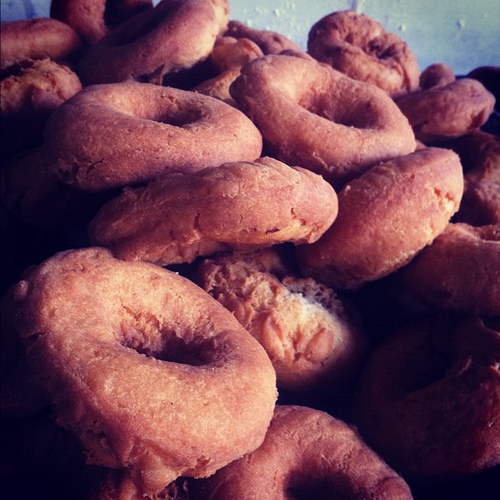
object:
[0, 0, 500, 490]
pile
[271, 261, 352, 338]
toppings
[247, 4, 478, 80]
counter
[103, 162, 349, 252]
donut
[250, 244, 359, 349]
frosting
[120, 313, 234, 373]
hole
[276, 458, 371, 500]
hole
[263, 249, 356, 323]
hole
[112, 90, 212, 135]
hole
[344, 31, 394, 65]
hole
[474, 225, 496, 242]
hole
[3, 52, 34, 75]
hole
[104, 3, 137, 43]
hole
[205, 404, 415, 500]
donuts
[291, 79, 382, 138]
hole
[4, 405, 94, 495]
donut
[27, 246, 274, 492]
fried donut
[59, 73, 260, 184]
donut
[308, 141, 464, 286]
fried donuts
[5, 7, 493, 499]
donuts on a pile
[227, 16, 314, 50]
donut crumbs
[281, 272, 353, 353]
odd topping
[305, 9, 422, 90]
deformed donut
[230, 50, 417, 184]
plain donut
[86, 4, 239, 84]
brown doughnut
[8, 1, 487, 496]
doughnuts mountain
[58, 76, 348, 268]
plain doughnuts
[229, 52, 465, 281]
brown doughnuts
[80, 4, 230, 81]
top doughnut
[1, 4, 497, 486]
photograph of donuts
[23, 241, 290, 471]
donut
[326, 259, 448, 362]
shadow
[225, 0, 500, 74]
wall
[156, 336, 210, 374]
shadow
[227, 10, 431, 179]
two donuts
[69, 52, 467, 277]
four donuts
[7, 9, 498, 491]
pile of donuts